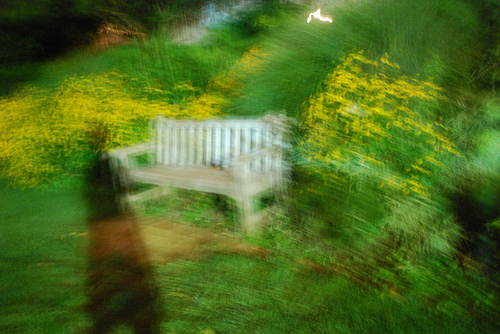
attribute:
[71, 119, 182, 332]
shadow — dark, long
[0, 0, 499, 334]
grass — tall, short, green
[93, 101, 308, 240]
bench — white, tan, small, blurry, wooden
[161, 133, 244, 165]
slats — white, vertical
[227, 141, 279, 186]
right arm — white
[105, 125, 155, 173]
left arm — white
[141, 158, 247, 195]
seat — tan, wooden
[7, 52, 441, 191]
flowers — yellow, blurry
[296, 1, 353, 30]
line — white, zig zagged, light